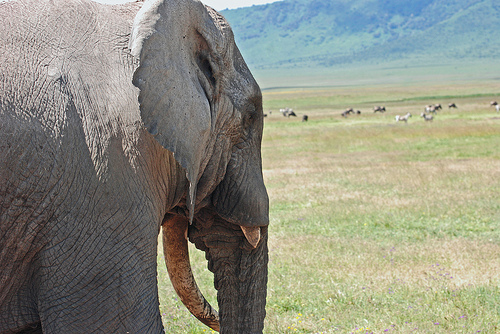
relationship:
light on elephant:
[2, 2, 163, 175] [1, 0, 271, 334]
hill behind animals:
[218, 1, 500, 74] [263, 101, 499, 127]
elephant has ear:
[1, 0, 271, 334] [129, 0, 222, 220]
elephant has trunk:
[1, 0, 271, 334] [188, 219, 269, 334]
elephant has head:
[1, 0, 271, 334] [163, 2, 270, 247]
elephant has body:
[1, 0, 271, 334] [2, 2, 170, 334]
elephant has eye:
[1, 0, 271, 334] [246, 104, 258, 127]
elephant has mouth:
[1, 0, 271, 334] [181, 206, 243, 229]